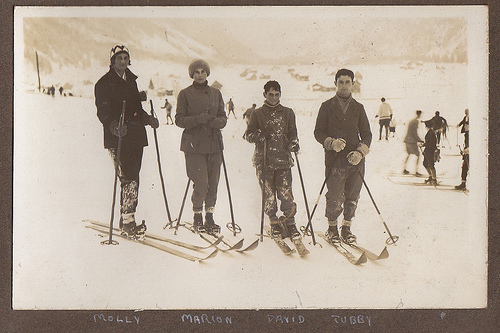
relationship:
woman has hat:
[173, 59, 227, 228] [188, 58, 210, 76]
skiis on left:
[85, 219, 223, 263] [15, 7, 219, 283]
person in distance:
[162, 95, 178, 122] [35, 28, 427, 126]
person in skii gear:
[97, 44, 155, 238] [94, 69, 154, 215]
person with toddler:
[376, 94, 391, 139] [391, 123, 396, 135]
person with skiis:
[97, 44, 155, 238] [85, 219, 223, 263]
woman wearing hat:
[173, 59, 227, 228] [188, 58, 210, 76]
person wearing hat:
[97, 44, 155, 238] [111, 44, 126, 54]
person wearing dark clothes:
[97, 44, 155, 238] [94, 69, 154, 215]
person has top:
[376, 94, 391, 139] [377, 101, 390, 114]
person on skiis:
[97, 44, 155, 238] [85, 219, 223, 263]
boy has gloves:
[314, 69, 372, 241] [331, 136, 359, 163]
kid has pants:
[314, 69, 372, 241] [321, 154, 363, 219]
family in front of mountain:
[92, 43, 368, 250] [26, 17, 466, 75]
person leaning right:
[97, 44, 155, 238] [321, 28, 459, 251]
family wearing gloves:
[92, 43, 368, 250] [331, 136, 359, 163]